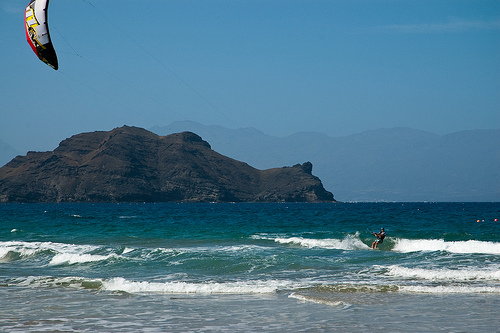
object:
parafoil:
[23, 1, 63, 71]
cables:
[83, 0, 376, 233]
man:
[370, 226, 387, 253]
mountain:
[1, 124, 338, 204]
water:
[0, 203, 498, 332]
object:
[19, 0, 63, 72]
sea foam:
[2, 238, 272, 267]